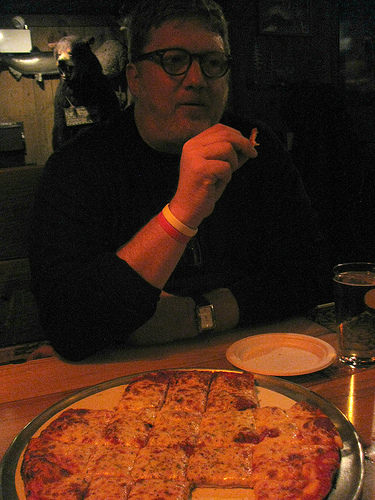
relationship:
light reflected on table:
[339, 361, 364, 425] [22, 355, 367, 495]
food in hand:
[251, 128, 259, 149] [168, 120, 261, 222]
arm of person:
[79, 113, 337, 294] [26, 17, 292, 377]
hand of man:
[177, 122, 258, 214] [28, 0, 326, 362]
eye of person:
[163, 55, 183, 72] [28, 2, 337, 291]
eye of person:
[205, 59, 221, 72] [28, 2, 337, 291]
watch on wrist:
[190, 292, 216, 341] [186, 296, 207, 337]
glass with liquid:
[330, 258, 373, 371] [332, 257, 372, 323]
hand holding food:
[177, 122, 258, 214] [247, 123, 261, 152]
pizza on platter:
[24, 369, 344, 495] [1, 362, 370, 496]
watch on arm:
[190, 292, 216, 337] [76, 176, 222, 283]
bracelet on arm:
[150, 189, 209, 255] [22, 135, 195, 367]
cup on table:
[331, 259, 374, 367] [1, 311, 371, 448]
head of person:
[119, 11, 238, 155] [17, 1, 350, 365]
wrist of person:
[147, 198, 201, 258] [17, 1, 350, 365]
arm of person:
[188, 292, 216, 341] [35, 6, 353, 299]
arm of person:
[32, 157, 194, 362] [25, 11, 332, 396]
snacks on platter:
[20, 366, 341, 495] [0, 365, 365, 500]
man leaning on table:
[129, 37, 357, 330] [11, 298, 339, 497]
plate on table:
[224, 331, 334, 379] [0, 301, 372, 499]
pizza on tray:
[20, 368, 342, 500] [0, 360, 355, 498]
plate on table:
[229, 326, 335, 379] [13, 320, 332, 497]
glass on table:
[331, 258, 373, 370] [0, 301, 372, 499]